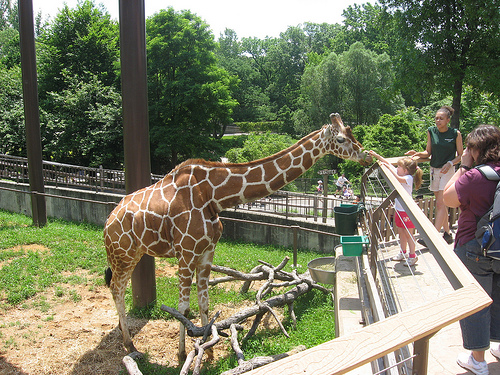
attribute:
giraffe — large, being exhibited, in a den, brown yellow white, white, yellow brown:
[92, 107, 374, 352]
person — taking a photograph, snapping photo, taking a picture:
[440, 127, 497, 372]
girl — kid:
[366, 142, 431, 268]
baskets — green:
[336, 227, 381, 260]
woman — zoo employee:
[419, 103, 461, 227]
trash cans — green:
[330, 192, 362, 234]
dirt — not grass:
[66, 311, 162, 374]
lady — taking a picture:
[457, 145, 499, 273]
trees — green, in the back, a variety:
[153, 3, 482, 152]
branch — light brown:
[232, 258, 315, 320]